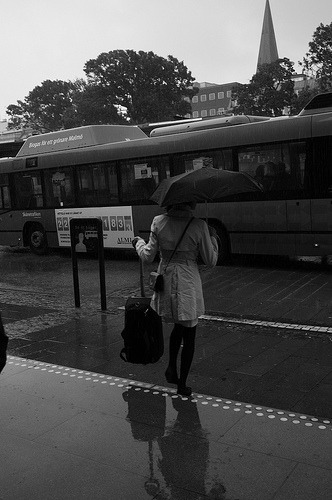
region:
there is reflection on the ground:
[143, 411, 224, 498]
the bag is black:
[120, 297, 164, 360]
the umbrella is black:
[160, 171, 259, 197]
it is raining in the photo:
[0, 206, 330, 491]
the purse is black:
[149, 271, 165, 288]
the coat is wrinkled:
[147, 221, 210, 317]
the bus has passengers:
[20, 140, 325, 260]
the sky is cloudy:
[53, 20, 221, 47]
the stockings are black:
[169, 334, 196, 376]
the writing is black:
[26, 134, 86, 141]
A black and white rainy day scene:
[7, 13, 325, 472]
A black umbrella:
[144, 162, 263, 211]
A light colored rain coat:
[132, 213, 222, 324]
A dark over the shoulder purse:
[146, 215, 196, 295]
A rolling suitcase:
[118, 237, 167, 368]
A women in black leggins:
[113, 166, 226, 394]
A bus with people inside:
[3, 111, 328, 273]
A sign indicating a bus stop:
[69, 217, 106, 313]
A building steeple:
[251, 2, 287, 84]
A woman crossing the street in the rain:
[114, 160, 264, 411]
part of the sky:
[187, 18, 227, 63]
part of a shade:
[174, 444, 200, 479]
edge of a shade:
[196, 433, 212, 460]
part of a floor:
[258, 469, 282, 497]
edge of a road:
[265, 393, 296, 405]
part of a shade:
[174, 431, 201, 473]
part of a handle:
[146, 455, 160, 480]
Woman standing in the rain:
[137, 190, 219, 411]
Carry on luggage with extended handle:
[115, 237, 170, 369]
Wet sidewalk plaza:
[2, 258, 331, 497]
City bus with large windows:
[1, 125, 323, 252]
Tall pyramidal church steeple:
[239, 0, 278, 87]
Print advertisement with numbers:
[43, 203, 146, 252]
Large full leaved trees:
[1, 39, 327, 122]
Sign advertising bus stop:
[62, 211, 117, 325]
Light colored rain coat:
[116, 195, 237, 356]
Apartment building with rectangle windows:
[134, 70, 294, 123]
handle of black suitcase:
[123, 231, 153, 297]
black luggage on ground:
[109, 291, 167, 364]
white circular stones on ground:
[53, 366, 199, 402]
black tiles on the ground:
[25, 396, 142, 469]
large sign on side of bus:
[37, 197, 152, 255]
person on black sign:
[70, 230, 89, 251]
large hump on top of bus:
[11, 120, 149, 153]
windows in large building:
[184, 81, 248, 109]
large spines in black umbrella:
[151, 152, 253, 209]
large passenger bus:
[62, 110, 301, 252]